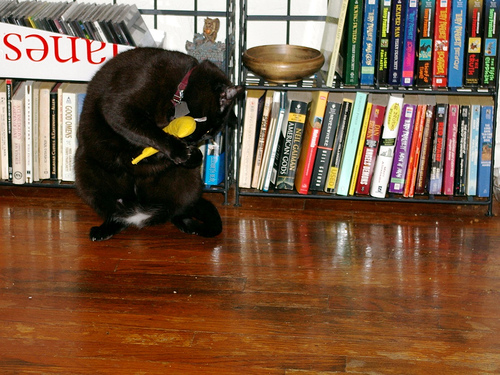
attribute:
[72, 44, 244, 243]
cat — black, white, standing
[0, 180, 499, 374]
floor — wooden, dark, beautiful, shiny, hardwood, brown, wood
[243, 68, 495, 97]
shelf — wire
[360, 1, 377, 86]
book — blue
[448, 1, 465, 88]
book — blue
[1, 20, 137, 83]
sign — upside down, white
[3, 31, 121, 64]
lettering — red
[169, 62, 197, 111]
collar — red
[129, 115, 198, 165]
toy — yellow, banana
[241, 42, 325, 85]
dish — small, brown, wooden, round, little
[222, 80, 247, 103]
ear — black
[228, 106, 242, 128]
ear — black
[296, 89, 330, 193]
book — red, yellow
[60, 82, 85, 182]
good omens book — white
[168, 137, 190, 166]
paw — black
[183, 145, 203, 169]
paw — black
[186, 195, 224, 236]
tail — black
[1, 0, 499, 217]
shelves — full, metal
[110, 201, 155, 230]
patch — white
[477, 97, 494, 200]
book — blue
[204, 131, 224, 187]
book — blue